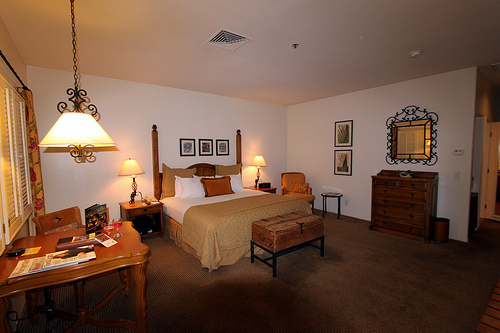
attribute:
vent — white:
[212, 32, 242, 50]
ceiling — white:
[183, 2, 283, 80]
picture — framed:
[333, 120, 354, 148]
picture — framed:
[334, 151, 354, 176]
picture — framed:
[218, 138, 231, 157]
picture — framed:
[199, 139, 212, 158]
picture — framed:
[178, 135, 195, 157]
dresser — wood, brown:
[367, 178, 432, 238]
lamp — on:
[254, 156, 264, 185]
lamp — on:
[122, 164, 142, 200]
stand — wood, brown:
[123, 202, 162, 226]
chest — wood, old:
[256, 212, 319, 243]